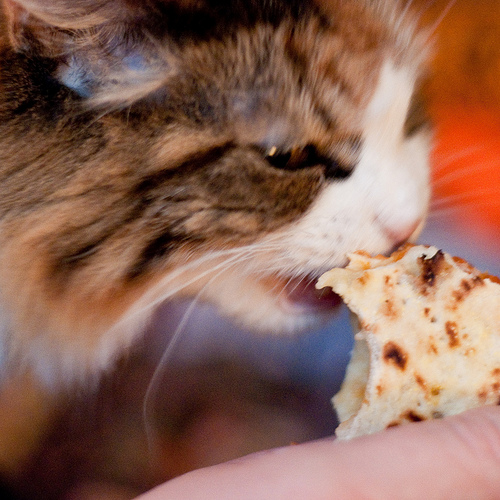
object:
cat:
[0, 0, 446, 397]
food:
[315, 242, 499, 441]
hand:
[128, 403, 499, 500]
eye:
[265, 140, 322, 171]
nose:
[376, 201, 424, 247]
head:
[35, 1, 436, 334]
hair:
[16, 0, 288, 31]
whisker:
[141, 237, 267, 464]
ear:
[4, 1, 175, 110]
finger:
[252, 403, 500, 498]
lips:
[280, 277, 344, 310]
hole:
[332, 217, 338, 223]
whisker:
[100, 216, 340, 471]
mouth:
[269, 252, 400, 316]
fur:
[2, 0, 173, 292]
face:
[222, 21, 435, 337]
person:
[131, 406, 500, 500]